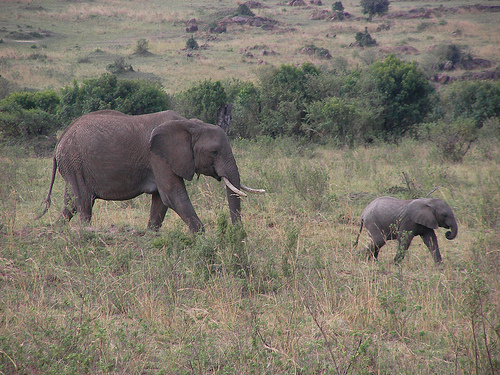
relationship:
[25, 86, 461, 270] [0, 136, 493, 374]
animals in field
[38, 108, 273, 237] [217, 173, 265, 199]
elephant has tusks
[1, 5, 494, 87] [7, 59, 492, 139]
field behind trees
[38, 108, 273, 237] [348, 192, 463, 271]
elephant behind elephant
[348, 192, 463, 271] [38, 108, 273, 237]
elephant in front of elephant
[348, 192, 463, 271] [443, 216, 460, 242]
elephant has trunk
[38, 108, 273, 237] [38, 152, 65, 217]
elephant has tail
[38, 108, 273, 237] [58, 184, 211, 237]
elephant has legs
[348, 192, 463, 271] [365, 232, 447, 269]
elephant has legs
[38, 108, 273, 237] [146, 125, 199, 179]
elephant has ear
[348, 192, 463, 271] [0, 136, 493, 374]
elephant in field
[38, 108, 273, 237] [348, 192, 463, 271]
elephant follows elephant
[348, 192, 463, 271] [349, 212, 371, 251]
elephant has tail